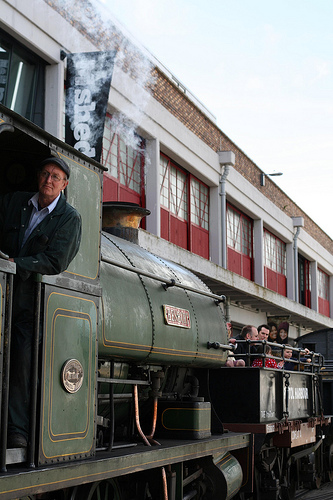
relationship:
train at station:
[31, 274, 315, 454] [62, 22, 312, 257]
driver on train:
[22, 154, 89, 273] [31, 274, 315, 454]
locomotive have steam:
[63, 121, 217, 348] [120, 71, 153, 163]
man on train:
[240, 326, 263, 347] [31, 274, 315, 454]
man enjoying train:
[240, 326, 263, 347] [2, 264, 333, 499]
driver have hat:
[22, 154, 89, 273] [40, 153, 76, 174]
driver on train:
[6, 154, 82, 413] [31, 274, 315, 454]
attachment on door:
[57, 355, 95, 399] [47, 289, 100, 466]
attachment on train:
[57, 355, 95, 399] [31, 274, 315, 454]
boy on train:
[298, 347, 313, 368] [31, 274, 315, 454]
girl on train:
[256, 346, 284, 369] [31, 274, 315, 454]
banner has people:
[265, 316, 290, 343] [268, 323, 284, 342]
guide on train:
[22, 154, 89, 273] [31, 274, 315, 454]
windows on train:
[172, 182, 217, 262] [31, 274, 315, 454]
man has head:
[240, 326, 273, 347] [259, 328, 267, 343]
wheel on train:
[303, 442, 330, 496] [31, 274, 315, 454]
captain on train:
[22, 154, 89, 273] [31, 274, 315, 454]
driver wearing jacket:
[6, 154, 82, 413] [6, 204, 77, 259]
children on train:
[262, 345, 310, 364] [31, 274, 315, 454]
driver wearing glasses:
[22, 154, 89, 273] [30, 166, 73, 190]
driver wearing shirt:
[6, 154, 82, 413] [30, 202, 57, 222]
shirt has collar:
[30, 202, 57, 222] [26, 192, 53, 211]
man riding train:
[240, 326, 263, 347] [31, 274, 315, 454]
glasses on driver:
[30, 166, 73, 190] [6, 154, 82, 413]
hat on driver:
[40, 153, 76, 174] [6, 154, 82, 413]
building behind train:
[140, 98, 332, 302] [31, 274, 315, 454]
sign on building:
[47, 39, 120, 157] [140, 98, 332, 302]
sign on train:
[281, 380, 319, 409] [31, 274, 315, 454]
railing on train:
[250, 342, 326, 368] [31, 274, 315, 454]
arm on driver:
[4, 250, 83, 275] [6, 154, 82, 413]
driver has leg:
[6, 154, 82, 413] [10, 292, 38, 432]